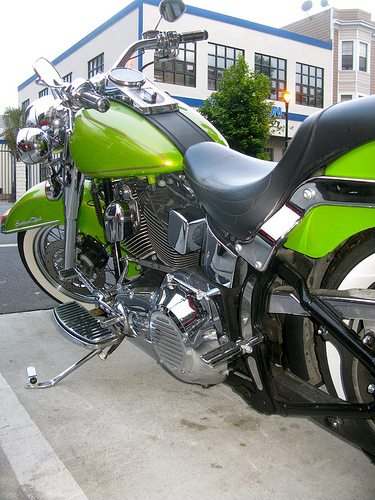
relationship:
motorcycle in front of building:
[0, 0, 375, 463] [14, 1, 333, 212]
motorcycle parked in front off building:
[0, 0, 375, 463] [14, 1, 333, 212]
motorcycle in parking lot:
[0, 0, 375, 463] [0, 198, 374, 497]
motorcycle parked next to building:
[0, 0, 375, 463] [14, 1, 333, 212]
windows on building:
[203, 39, 246, 96] [8, 8, 335, 181]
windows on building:
[295, 59, 325, 106] [8, 8, 335, 181]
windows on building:
[251, 50, 286, 101] [8, 8, 335, 181]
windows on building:
[151, 32, 197, 85] [8, 8, 335, 181]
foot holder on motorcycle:
[200, 331, 265, 365] [0, 0, 375, 463]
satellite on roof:
[302, 0, 314, 19] [271, 4, 373, 27]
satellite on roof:
[321, 1, 330, 9] [271, 4, 373, 27]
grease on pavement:
[174, 416, 209, 432] [3, 310, 371, 494]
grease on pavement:
[223, 408, 258, 434] [3, 310, 371, 494]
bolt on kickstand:
[21, 364, 39, 389] [24, 328, 125, 395]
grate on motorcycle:
[143, 312, 203, 380] [17, 32, 368, 356]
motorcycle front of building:
[23, 77, 373, 467] [70, 10, 333, 177]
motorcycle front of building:
[0, 0, 375, 463] [130, 6, 372, 95]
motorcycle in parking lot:
[0, 0, 375, 463] [2, 282, 38, 332]